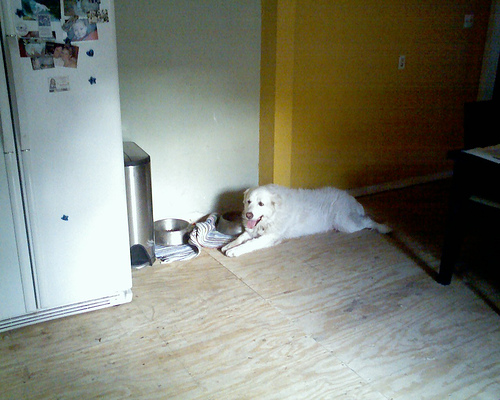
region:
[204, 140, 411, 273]
a dog laying on floor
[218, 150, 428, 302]
a white dog laying on floor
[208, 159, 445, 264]
a dog panting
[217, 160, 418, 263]
a white dog panting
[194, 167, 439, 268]
a dog laying down panting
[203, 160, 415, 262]
a white dog laying down panting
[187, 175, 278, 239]
a bowl of dog food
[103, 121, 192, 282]
a silver garbage can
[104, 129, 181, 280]
a silver trash can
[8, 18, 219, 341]
a white fridge with pictures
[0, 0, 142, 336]
a two door white referigator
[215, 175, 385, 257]
a white dog laying on floor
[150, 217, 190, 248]
a brushed aluminum dog dish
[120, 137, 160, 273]
a brushed aluminum storage container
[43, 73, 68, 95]
a rectangular refrigerator magnet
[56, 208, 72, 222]
a small refrigerator magnet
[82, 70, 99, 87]
a small refrigerator magnet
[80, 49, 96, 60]
a small refrigerator magnet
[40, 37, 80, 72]
a family photograph on refrigerator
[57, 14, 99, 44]
a family photograph on refrigerator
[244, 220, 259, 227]
The pink tongue of the dog.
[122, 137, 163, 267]
The silver garbage can next to the fridge.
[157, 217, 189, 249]
The silver bowl next to the trash can.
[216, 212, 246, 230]
The silver bowl next to the dog.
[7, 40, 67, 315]
The handles on the double doors of the fridge.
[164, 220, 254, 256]
The striped rug under the bowls on the floor.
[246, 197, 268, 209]
The eyes of the dog.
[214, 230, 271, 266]
The front legs of the dog.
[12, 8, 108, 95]
The pictures on the fridge door.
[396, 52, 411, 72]
The light socket on the yellow wall.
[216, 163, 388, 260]
A dog on the ground.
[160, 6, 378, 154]
The white and yellow wall.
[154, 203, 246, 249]
Food and water bowl.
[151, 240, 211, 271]
A rug on the ground.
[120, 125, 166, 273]
A trash can near fridge.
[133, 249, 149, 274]
pedal of the trash can.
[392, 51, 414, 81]
socket on the wall.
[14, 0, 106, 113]
pictures on the fridge.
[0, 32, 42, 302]
handle on the fridge.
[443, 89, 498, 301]
A chair at the table.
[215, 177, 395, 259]
a dog laying on the floor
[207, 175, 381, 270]
a white dog in the kitchen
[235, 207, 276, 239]
pink dog tongue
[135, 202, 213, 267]
a silver dog dish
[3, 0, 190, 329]
the refrigerator in the kitchen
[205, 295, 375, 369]
a wooden floor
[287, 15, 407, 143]
a yellow painted wall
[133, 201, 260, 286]
towel underneath the dog bowls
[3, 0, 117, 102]
pictures and magnets on the fridge